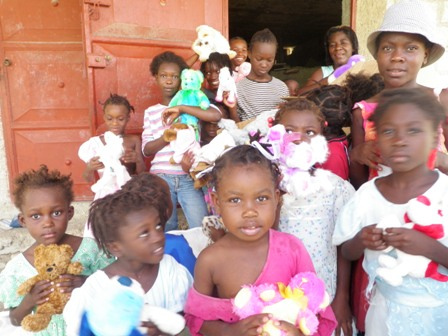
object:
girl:
[199, 52, 231, 93]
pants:
[154, 173, 209, 233]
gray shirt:
[236, 76, 291, 122]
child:
[0, 165, 107, 336]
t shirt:
[184, 228, 339, 336]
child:
[229, 36, 249, 75]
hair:
[231, 37, 248, 43]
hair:
[249, 28, 278, 53]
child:
[331, 86, 448, 335]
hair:
[368, 87, 443, 132]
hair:
[210, 144, 282, 192]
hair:
[12, 165, 77, 211]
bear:
[169, 68, 211, 141]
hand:
[353, 223, 388, 252]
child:
[82, 94, 146, 202]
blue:
[180, 90, 199, 105]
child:
[59, 190, 194, 336]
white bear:
[77, 130, 130, 201]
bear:
[16, 243, 85, 332]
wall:
[354, 0, 448, 95]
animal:
[231, 271, 333, 334]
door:
[1, 0, 236, 205]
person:
[348, 1, 447, 192]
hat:
[365, 0, 444, 69]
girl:
[266, 95, 357, 313]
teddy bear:
[266, 123, 357, 309]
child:
[235, 29, 289, 121]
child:
[180, 144, 338, 335]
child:
[141, 50, 223, 232]